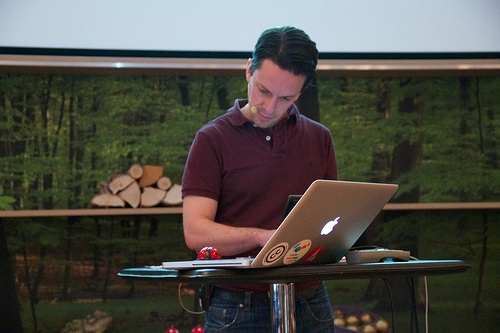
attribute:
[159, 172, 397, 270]
laptop — white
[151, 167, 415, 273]
laptop — grey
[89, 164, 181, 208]
wood — stacked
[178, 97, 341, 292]
shirt — maroon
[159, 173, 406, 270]
computer — apple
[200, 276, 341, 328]
jeans — blue, black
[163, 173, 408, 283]
laptop — on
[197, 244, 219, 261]
mouse — ladybug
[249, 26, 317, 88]
hair — black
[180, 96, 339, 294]
polo shirt — burgundy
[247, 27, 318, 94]
hair — dark